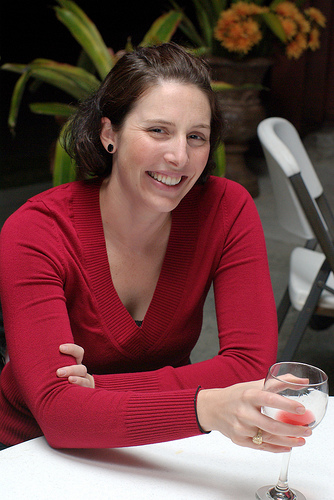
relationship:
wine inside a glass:
[271, 406, 318, 441] [254, 360, 329, 500]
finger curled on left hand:
[57, 341, 84, 365] [51, 341, 95, 390]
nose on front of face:
[162, 130, 192, 172] [119, 77, 213, 214]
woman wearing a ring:
[1, 39, 315, 456] [248, 425, 266, 448]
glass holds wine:
[254, 360, 329, 500] [271, 406, 318, 441]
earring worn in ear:
[105, 143, 115, 154] [95, 114, 119, 156]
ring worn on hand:
[248, 425, 266, 448] [211, 371, 316, 455]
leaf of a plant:
[27, 99, 80, 117] [1, 0, 271, 187]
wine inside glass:
[271, 406, 318, 441] [254, 360, 329, 500]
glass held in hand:
[254, 360, 329, 500] [211, 371, 316, 455]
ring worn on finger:
[248, 425, 266, 448] [241, 421, 305, 450]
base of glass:
[256, 483, 310, 499] [254, 360, 329, 500]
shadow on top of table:
[31, 434, 333, 499] [0, 372, 333, 499]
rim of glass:
[269, 360, 329, 388] [254, 360, 329, 500]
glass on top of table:
[254, 360, 329, 500] [0, 372, 333, 499]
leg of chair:
[278, 312, 320, 380] [254, 115, 333, 375]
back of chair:
[254, 114, 330, 243] [254, 115, 333, 375]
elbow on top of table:
[29, 370, 96, 454] [0, 372, 333, 499]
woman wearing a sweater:
[1, 39, 315, 456] [0, 172, 281, 456]